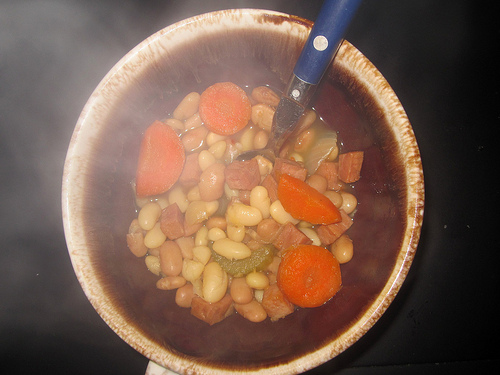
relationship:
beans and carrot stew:
[126, 88, 360, 324] [129, 79, 361, 319]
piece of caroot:
[311, 274, 322, 282] [278, 245, 342, 312]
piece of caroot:
[311, 200, 323, 210] [276, 175, 341, 226]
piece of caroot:
[227, 101, 239, 108] [197, 80, 253, 137]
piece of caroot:
[161, 151, 171, 160] [137, 122, 187, 198]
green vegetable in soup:
[207, 240, 276, 277] [121, 71, 372, 328]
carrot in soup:
[276, 242, 345, 311] [151, 102, 330, 308]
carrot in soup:
[198, 81, 249, 138] [83, 29, 405, 370]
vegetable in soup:
[176, 154, 332, 291] [85, 25, 393, 349]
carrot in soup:
[198, 81, 249, 138] [100, 46, 411, 359]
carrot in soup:
[138, 121, 186, 200] [100, 46, 411, 359]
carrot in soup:
[277, 175, 341, 226] [100, 46, 411, 359]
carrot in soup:
[276, 242, 345, 311] [100, 46, 411, 359]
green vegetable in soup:
[207, 240, 276, 277] [100, 46, 411, 359]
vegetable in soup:
[133, 79, 366, 319] [316, 179, 373, 279]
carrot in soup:
[276, 242, 345, 311] [133, 62, 399, 254]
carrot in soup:
[276, 242, 345, 311] [49, 19, 409, 358]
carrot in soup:
[276, 242, 345, 311] [83, 29, 405, 370]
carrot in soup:
[277, 175, 341, 226] [83, 29, 405, 370]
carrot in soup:
[138, 121, 186, 200] [83, 29, 405, 370]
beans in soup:
[126, 88, 360, 324] [83, 29, 405, 370]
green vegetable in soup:
[207, 240, 276, 277] [33, 12, 453, 374]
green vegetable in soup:
[197, 238, 279, 283] [121, 71, 372, 328]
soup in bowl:
[68, 14, 426, 374] [56, 10, 430, 372]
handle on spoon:
[242, 5, 370, 157] [230, 5, 363, 197]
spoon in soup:
[228, 24, 350, 185] [112, 104, 353, 304]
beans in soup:
[153, 88, 360, 310] [85, 25, 393, 349]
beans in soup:
[126, 88, 360, 324] [121, 71, 372, 328]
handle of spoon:
[263, 5, 356, 159] [248, 5, 366, 188]